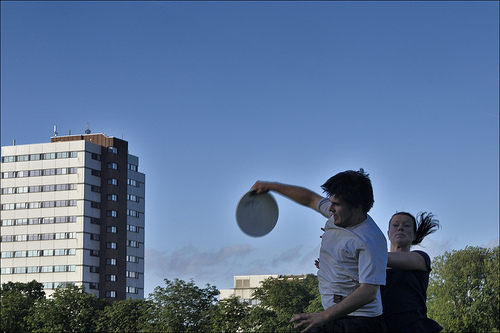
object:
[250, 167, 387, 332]
man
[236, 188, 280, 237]
frisbee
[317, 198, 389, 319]
tee shirt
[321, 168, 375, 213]
hair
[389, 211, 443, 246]
hair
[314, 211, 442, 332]
woman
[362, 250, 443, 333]
shirt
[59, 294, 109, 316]
leaf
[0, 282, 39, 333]
tree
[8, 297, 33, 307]
leaf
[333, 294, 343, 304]
logo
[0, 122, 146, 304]
building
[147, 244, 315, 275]
cloud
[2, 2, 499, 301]
sky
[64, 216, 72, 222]
window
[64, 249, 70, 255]
window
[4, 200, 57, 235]
window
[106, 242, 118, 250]
window